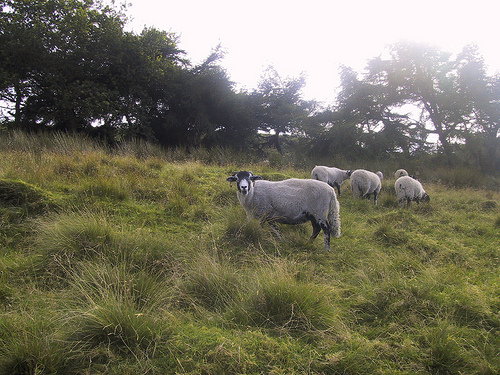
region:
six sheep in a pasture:
[231, 165, 431, 245]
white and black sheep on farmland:
[225, 164, 431, 257]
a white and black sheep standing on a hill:
[227, 169, 340, 250]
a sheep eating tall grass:
[395, 175, 432, 207]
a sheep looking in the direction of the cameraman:
[225, 170, 341, 249]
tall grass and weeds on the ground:
[0, 260, 497, 374]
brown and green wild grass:
[0, 255, 167, 373]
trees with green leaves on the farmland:
[2, 35, 498, 160]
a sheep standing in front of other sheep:
[224, 170, 341, 250]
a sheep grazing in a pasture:
[393, 175, 430, 208]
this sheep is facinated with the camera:
[205, 157, 402, 292]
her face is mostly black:
[222, 150, 316, 238]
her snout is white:
[212, 155, 297, 225]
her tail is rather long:
[221, 155, 358, 262]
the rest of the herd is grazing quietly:
[185, 148, 458, 245]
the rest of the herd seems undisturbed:
[313, 148, 439, 215]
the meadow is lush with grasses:
[27, 152, 201, 361]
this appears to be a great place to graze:
[28, 147, 218, 354]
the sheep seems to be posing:
[221, 150, 353, 262]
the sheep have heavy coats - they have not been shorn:
[221, 148, 460, 245]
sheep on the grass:
[203, 141, 450, 256]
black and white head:
[221, 164, 261, 191]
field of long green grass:
[5, 121, 499, 371]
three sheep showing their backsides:
[304, 150, 429, 212]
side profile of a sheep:
[222, 142, 352, 266]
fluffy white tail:
[322, 186, 345, 235]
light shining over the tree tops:
[150, 4, 401, 100]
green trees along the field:
[2, 2, 499, 166]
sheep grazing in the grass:
[389, 177, 444, 210]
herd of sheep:
[204, 147, 461, 246]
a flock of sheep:
[184, 140, 452, 252]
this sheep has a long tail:
[179, 160, 349, 266]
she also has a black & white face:
[211, 162, 351, 239]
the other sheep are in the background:
[306, 154, 446, 230]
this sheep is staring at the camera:
[201, 161, 356, 269]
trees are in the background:
[38, 0, 494, 174]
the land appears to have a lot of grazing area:
[26, 151, 244, 355]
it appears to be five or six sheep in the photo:
[222, 151, 453, 268]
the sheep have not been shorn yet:
[206, 132, 438, 272]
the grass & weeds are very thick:
[46, 172, 266, 368]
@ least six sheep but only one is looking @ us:
[209, 158, 435, 263]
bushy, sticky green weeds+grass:
[0, 127, 498, 374]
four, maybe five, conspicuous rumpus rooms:
[307, 160, 435, 212]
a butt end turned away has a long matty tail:
[345, 169, 369, 209]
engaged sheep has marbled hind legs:
[299, 213, 333, 254]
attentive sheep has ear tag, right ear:
[223, 176, 235, 193]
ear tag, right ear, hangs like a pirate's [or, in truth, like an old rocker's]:
[225, 178, 236, 194]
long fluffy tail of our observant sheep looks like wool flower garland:
[326, 186, 347, 243]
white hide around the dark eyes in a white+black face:
[222, 166, 267, 199]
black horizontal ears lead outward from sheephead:
[223, 173, 265, 194]